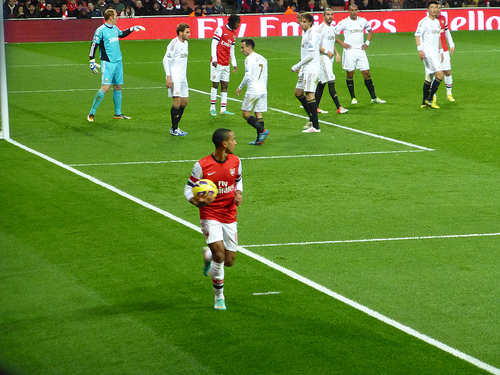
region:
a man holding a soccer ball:
[168, 123, 261, 313]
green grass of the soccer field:
[64, 266, 178, 335]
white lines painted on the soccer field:
[288, 220, 390, 323]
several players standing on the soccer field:
[7, 0, 477, 162]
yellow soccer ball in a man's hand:
[188, 178, 221, 208]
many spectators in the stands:
[12, 1, 268, 21]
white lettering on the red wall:
[453, 13, 498, 29]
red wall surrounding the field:
[27, 22, 84, 39]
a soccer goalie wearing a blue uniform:
[76, 3, 144, 124]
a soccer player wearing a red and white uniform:
[177, 125, 267, 316]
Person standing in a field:
[168, 117, 259, 351]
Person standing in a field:
[413, 2, 450, 113]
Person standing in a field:
[340, 4, 387, 114]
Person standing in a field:
[315, 4, 343, 116]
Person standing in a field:
[291, 10, 328, 129]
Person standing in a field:
[232, 30, 277, 145]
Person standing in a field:
[204, 7, 243, 122]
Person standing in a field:
[150, 15, 200, 137]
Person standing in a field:
[85, 6, 142, 133]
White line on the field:
[260, 237, 447, 374]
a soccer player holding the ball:
[171, 119, 262, 311]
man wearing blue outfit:
[75, 9, 152, 124]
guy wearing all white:
[150, 17, 205, 145]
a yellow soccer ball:
[190, 176, 219, 204]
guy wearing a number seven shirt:
[223, 37, 295, 146]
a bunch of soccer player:
[25, 0, 457, 147]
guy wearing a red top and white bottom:
[200, 15, 250, 115]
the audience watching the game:
[10, 0, 497, 17]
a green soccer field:
[3, 20, 498, 370]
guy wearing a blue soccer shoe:
[235, 31, 283, 151]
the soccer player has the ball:
[91, 91, 316, 325]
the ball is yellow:
[150, 83, 311, 368]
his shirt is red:
[151, 75, 281, 249]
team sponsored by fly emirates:
[142, 63, 357, 371]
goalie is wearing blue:
[64, 9, 258, 219]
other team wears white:
[152, 5, 457, 152]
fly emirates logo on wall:
[168, 6, 489, 128]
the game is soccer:
[78, 6, 480, 303]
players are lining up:
[78, 33, 459, 350]